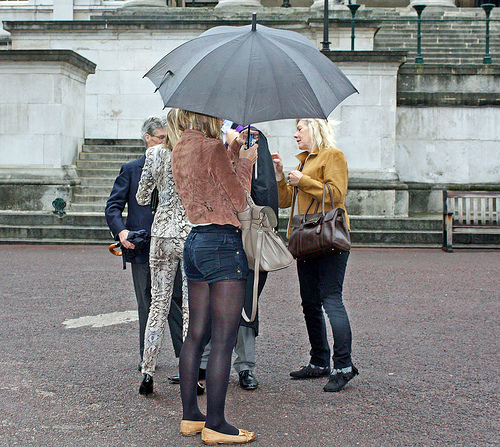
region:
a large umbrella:
[139, 10, 362, 122]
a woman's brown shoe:
[198, 423, 259, 445]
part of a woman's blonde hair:
[169, 102, 225, 137]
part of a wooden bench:
[438, 187, 498, 252]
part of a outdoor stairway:
[73, 135, 142, 216]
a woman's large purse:
[287, 178, 352, 259]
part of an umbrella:
[103, 228, 150, 259]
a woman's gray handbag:
[233, 185, 294, 322]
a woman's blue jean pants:
[296, 251, 351, 367]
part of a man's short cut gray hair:
[138, 114, 167, 138]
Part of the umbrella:
[217, 53, 282, 92]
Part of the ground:
[396, 322, 434, 377]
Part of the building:
[430, 131, 470, 167]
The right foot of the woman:
[201, 420, 260, 445]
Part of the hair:
[146, 120, 159, 127]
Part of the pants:
[327, 273, 339, 298]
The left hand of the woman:
[285, 167, 304, 189]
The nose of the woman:
[292, 127, 300, 139]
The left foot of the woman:
[321, 364, 364, 394]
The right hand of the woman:
[237, 141, 260, 166]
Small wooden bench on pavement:
[437, 187, 489, 254]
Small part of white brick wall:
[20, 72, 71, 104]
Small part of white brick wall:
[5, 124, 37, 146]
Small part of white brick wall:
[37, 134, 72, 167]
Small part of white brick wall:
[84, 109, 124, 139]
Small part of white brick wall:
[120, 104, 142, 137]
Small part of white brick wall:
[98, 65, 135, 115]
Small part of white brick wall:
[13, 17, 50, 50]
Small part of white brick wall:
[45, 5, 104, 41]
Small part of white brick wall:
[100, 7, 169, 39]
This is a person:
[285, 106, 416, 410]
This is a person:
[226, 102, 286, 439]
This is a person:
[169, 91, 249, 436]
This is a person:
[109, 103, 186, 403]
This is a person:
[133, 101, 210, 442]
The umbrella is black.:
[131, 8, 371, 122]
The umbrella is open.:
[151, 7, 349, 128]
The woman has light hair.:
[287, 114, 354, 151]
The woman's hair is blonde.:
[288, 111, 351, 158]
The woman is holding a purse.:
[285, 175, 367, 265]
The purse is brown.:
[286, 173, 353, 266]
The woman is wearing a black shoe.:
[322, 348, 369, 400]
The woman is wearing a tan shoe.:
[198, 418, 261, 444]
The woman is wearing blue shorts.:
[160, 213, 255, 303]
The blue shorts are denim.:
[175, 217, 251, 288]